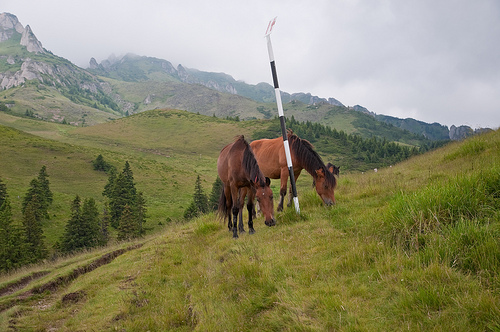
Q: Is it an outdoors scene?
A: Yes, it is outdoors.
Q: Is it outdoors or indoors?
A: It is outdoors.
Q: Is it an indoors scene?
A: No, it is outdoors.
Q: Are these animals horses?
A: Yes, all the animals are horses.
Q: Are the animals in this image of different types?
A: No, all the animals are horses.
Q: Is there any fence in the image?
A: No, there are no fences.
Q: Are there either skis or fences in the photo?
A: No, there are no fences or skis.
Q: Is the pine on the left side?
A: Yes, the pine is on the left of the image.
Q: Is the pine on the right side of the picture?
A: No, the pine is on the left of the image.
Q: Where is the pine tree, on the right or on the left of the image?
A: The pine tree is on the left of the image.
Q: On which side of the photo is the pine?
A: The pine is on the left of the image.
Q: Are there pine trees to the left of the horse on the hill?
A: Yes, there is a pine tree to the left of the horse.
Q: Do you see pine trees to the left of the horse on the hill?
A: Yes, there is a pine tree to the left of the horse.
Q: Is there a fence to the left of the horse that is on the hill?
A: No, there is a pine tree to the left of the horse.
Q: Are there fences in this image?
A: No, there are no fences.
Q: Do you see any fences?
A: No, there are no fences.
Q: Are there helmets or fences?
A: No, there are no fences or helmets.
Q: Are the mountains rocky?
A: Yes, the mountains are rocky.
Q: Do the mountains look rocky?
A: Yes, the mountains are rocky.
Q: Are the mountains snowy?
A: No, the mountains are rocky.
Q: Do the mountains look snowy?
A: No, the mountains are rocky.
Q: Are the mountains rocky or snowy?
A: The mountains are rocky.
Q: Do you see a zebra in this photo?
A: No, there are no zebras.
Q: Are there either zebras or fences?
A: No, there are no zebras or fences.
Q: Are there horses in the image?
A: Yes, there is a horse.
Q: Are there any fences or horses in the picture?
A: Yes, there is a horse.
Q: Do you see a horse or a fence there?
A: Yes, there is a horse.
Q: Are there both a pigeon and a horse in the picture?
A: No, there is a horse but no pigeons.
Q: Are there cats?
A: No, there are no cats.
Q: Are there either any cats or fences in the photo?
A: No, there are no cats or fences.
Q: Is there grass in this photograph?
A: Yes, there is grass.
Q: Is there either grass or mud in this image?
A: Yes, there is grass.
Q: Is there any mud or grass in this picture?
A: Yes, there is grass.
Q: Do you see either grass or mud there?
A: Yes, there is grass.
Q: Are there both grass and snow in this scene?
A: No, there is grass but no snow.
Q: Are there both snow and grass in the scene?
A: No, there is grass but no snow.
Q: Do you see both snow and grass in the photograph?
A: No, there is grass but no snow.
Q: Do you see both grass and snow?
A: No, there is grass but no snow.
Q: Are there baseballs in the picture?
A: No, there are no baseballs.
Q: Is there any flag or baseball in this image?
A: No, there are no baseballs or flags.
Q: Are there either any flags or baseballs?
A: No, there are no baseballs or flags.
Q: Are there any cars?
A: No, there are no cars.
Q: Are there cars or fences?
A: No, there are no cars or fences.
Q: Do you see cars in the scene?
A: No, there are no cars.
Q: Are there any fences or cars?
A: No, there are no cars or fences.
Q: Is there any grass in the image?
A: Yes, there is grass.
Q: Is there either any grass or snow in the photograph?
A: Yes, there is grass.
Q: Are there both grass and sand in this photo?
A: No, there is grass but no sand.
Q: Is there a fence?
A: No, there are no fences.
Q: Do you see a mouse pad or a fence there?
A: No, there are no fences or mouse pads.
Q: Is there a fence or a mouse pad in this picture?
A: No, there are no fences or mouse pads.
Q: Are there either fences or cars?
A: No, there are no cars or fences.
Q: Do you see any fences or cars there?
A: No, there are no cars or fences.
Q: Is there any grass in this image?
A: Yes, there is grass.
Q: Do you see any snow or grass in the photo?
A: Yes, there is grass.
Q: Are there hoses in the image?
A: No, there are no hoses.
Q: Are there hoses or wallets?
A: No, there are no hoses or wallets.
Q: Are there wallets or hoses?
A: No, there are no hoses or wallets.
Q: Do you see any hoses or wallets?
A: No, there are no hoses or wallets.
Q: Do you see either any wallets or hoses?
A: No, there are no hoses or wallets.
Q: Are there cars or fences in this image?
A: No, there are no cars or fences.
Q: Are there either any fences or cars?
A: No, there are no cars or fences.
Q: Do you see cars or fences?
A: No, there are no cars or fences.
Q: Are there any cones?
A: No, there are no cones.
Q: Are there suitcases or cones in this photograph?
A: No, there are no cones or suitcases.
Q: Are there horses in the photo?
A: Yes, there is a horse.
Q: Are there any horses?
A: Yes, there is a horse.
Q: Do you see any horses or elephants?
A: Yes, there is a horse.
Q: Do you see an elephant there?
A: No, there are no elephants.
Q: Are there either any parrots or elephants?
A: No, there are no elephants or parrots.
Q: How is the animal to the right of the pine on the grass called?
A: The animal is a horse.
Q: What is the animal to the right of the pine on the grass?
A: The animal is a horse.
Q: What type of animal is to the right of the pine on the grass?
A: The animal is a horse.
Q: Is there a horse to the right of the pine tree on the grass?
A: Yes, there is a horse to the right of the pine.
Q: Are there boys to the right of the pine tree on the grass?
A: No, there is a horse to the right of the pine tree.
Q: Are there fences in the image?
A: No, there are no fences.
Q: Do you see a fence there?
A: No, there are no fences.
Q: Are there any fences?
A: No, there are no fences.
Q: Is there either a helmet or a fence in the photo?
A: No, there are no fences or helmets.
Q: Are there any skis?
A: No, there are no skis.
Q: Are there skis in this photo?
A: No, there are no skis.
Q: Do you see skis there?
A: No, there are no skis.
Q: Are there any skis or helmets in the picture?
A: No, there are no skis or helmets.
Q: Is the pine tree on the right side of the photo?
A: No, the pine tree is on the left of the image.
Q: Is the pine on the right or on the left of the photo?
A: The pine is on the left of the image.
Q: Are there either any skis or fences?
A: No, there are no skis or fences.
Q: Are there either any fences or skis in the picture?
A: No, there are no skis or fences.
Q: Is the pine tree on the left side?
A: Yes, the pine tree is on the left of the image.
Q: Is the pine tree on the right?
A: No, the pine tree is on the left of the image.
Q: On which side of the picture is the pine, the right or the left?
A: The pine is on the left of the image.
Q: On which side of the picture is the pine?
A: The pine is on the left of the image.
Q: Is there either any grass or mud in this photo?
A: Yes, there is grass.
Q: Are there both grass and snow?
A: No, there is grass but no snow.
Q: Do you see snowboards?
A: No, there are no snowboards.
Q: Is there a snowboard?
A: No, there are no snowboards.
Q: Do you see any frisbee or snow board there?
A: No, there are no snowboards or frisbees.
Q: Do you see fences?
A: No, there are no fences.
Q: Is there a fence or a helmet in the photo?
A: No, there are no fences or helmets.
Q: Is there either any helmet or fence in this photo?
A: No, there are no fences or helmets.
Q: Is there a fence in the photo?
A: No, there are no fences.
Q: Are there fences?
A: No, there are no fences.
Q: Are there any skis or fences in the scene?
A: No, there are no fences or skis.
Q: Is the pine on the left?
A: Yes, the pine is on the left of the image.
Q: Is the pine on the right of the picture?
A: No, the pine is on the left of the image.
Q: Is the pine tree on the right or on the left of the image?
A: The pine tree is on the left of the image.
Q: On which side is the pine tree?
A: The pine tree is on the left of the image.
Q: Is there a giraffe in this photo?
A: No, there are no giraffes.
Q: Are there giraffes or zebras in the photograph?
A: No, there are no giraffes or zebras.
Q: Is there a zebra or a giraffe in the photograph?
A: No, there are no giraffes or zebras.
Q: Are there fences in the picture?
A: No, there are no fences.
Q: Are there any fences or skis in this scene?
A: No, there are no fences or skis.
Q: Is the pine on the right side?
A: No, the pine is on the left of the image.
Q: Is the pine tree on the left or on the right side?
A: The pine tree is on the left of the image.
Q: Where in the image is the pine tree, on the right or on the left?
A: The pine tree is on the left of the image.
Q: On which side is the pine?
A: The pine is on the left of the image.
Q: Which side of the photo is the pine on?
A: The pine is on the left of the image.